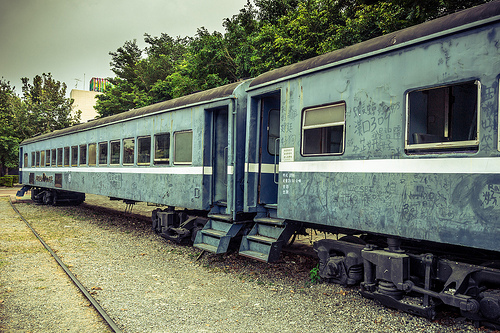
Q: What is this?
A: Train.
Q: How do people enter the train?
A: Steps.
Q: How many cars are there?
A: Two.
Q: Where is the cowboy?
A: No cowboy.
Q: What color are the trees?
A: Green.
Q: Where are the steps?
A: Leading to train.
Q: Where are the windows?
A: On the side of the train.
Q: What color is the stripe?
A: White.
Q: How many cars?
A: 2.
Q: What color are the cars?
A: Blue.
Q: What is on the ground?
A: Tracks.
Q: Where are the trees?
A: Behind the train cars.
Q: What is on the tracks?
A: Train.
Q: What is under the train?
A: Gravel.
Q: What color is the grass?
A: Green.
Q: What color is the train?
A: Blue.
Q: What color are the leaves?
A: Green.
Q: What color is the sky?
A: Gray.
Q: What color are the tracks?
A: Gray.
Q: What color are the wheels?
A: Gray.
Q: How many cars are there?
A: 2.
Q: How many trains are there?
A: One.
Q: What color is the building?
A: Cream.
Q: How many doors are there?
A: 2.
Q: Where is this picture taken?
A: A railway.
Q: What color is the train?
A: Blue.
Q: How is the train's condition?
A: Old.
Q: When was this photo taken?
A: During the day.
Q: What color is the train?
A: Blue.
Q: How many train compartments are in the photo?
A: 2.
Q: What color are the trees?
A: Green.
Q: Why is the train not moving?
A: It is not on tracks.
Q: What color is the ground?
A: Brown.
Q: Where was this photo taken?
A: By an abandoned train.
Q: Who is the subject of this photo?
A: The train.